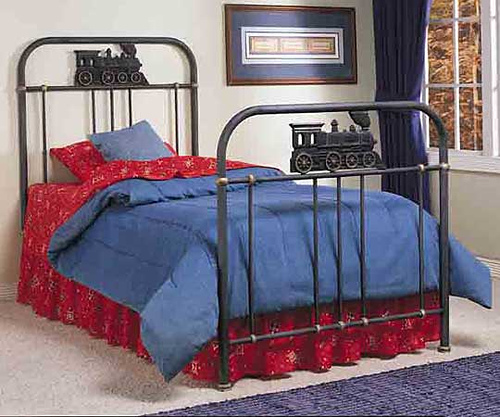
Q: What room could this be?
A: It is a bedroom.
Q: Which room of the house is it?
A: It is a bedroom.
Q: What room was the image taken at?
A: It was taken at the bedroom.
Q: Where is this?
A: This is at the bedroom.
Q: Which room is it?
A: It is a bedroom.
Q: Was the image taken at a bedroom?
A: Yes, it was taken in a bedroom.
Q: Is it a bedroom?
A: Yes, it is a bedroom.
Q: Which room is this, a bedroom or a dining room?
A: It is a bedroom.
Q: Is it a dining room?
A: No, it is a bedroom.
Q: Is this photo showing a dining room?
A: No, the picture is showing a bedroom.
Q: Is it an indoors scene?
A: Yes, it is indoors.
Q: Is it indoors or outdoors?
A: It is indoors.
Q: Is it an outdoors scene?
A: No, it is indoors.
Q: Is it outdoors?
A: No, it is indoors.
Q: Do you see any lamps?
A: No, there are no lamps.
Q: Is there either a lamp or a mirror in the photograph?
A: No, there are no lamps or mirrors.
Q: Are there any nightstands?
A: No, there are no nightstands.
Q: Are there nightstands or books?
A: No, there are no nightstands or books.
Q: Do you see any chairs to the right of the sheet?
A: No, there is a comforter to the right of the sheet.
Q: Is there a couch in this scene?
A: No, there are no couches.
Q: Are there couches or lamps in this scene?
A: No, there are no couches or lamps.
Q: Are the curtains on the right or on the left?
A: The curtains are on the right of the image.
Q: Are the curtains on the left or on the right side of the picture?
A: The curtains are on the right of the image.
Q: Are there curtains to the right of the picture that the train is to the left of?
A: Yes, there are curtains to the right of the picture.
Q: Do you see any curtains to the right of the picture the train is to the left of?
A: Yes, there are curtains to the right of the picture.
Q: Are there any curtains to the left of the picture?
A: No, the curtains are to the right of the picture.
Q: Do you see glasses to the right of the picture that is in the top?
A: No, there are curtains to the right of the picture.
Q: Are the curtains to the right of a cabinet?
A: No, the curtains are to the right of the picture.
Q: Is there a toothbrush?
A: No, there are no toothbrushes.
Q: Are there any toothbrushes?
A: No, there are no toothbrushes.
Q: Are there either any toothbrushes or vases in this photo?
A: No, there are no toothbrushes or vases.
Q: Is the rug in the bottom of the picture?
A: Yes, the rug is in the bottom of the image.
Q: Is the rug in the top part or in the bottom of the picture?
A: The rug is in the bottom of the image.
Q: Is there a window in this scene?
A: Yes, there is a window.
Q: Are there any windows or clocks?
A: Yes, there is a window.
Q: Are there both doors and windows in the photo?
A: No, there is a window but no doors.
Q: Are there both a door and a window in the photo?
A: No, there is a window but no doors.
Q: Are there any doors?
A: No, there are no doors.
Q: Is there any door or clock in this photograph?
A: No, there are no doors or clocks.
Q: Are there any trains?
A: Yes, there is a train.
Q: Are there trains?
A: Yes, there is a train.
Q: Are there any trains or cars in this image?
A: Yes, there is a train.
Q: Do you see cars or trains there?
A: Yes, there is a train.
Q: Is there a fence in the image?
A: No, there are no fences.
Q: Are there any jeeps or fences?
A: No, there are no fences or jeeps.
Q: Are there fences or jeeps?
A: No, there are no fences or jeeps.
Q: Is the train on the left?
A: Yes, the train is on the left of the image.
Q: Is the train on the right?
A: No, the train is on the left of the image.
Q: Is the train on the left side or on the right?
A: The train is on the left of the image.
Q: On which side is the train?
A: The train is on the left of the image.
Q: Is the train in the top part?
A: Yes, the train is in the top of the image.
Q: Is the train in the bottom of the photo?
A: No, the train is in the top of the image.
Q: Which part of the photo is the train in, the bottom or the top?
A: The train is in the top of the image.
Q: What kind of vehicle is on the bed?
A: The vehicle is a train.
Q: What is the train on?
A: The train is on the bed.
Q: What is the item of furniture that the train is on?
A: The piece of furniture is a bed.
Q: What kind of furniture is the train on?
A: The train is on the bed.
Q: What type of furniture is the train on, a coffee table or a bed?
A: The train is on a bed.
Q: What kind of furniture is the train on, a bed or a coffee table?
A: The train is on a bed.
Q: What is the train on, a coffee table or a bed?
A: The train is on a bed.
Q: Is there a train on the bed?
A: Yes, there is a train on the bed.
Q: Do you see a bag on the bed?
A: No, there is a train on the bed.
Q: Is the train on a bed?
A: Yes, the train is on a bed.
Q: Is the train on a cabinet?
A: No, the train is on a bed.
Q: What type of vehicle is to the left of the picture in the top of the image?
A: The vehicle is a train.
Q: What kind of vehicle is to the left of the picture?
A: The vehicle is a train.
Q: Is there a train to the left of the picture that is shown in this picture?
A: Yes, there is a train to the left of the picture.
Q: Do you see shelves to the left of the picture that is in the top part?
A: No, there is a train to the left of the picture.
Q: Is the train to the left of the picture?
A: Yes, the train is to the left of the picture.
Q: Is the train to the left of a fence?
A: No, the train is to the left of the picture.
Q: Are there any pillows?
A: Yes, there is a pillow.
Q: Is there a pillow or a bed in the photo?
A: Yes, there is a pillow.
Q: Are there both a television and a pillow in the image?
A: No, there is a pillow but no televisions.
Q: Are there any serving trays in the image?
A: No, there are no serving trays.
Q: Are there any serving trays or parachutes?
A: No, there are no serving trays or parachutes.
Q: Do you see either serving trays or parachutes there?
A: No, there are no serving trays or parachutes.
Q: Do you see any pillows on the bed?
A: Yes, there is a pillow on the bed.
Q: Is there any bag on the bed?
A: No, there is a pillow on the bed.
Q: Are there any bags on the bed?
A: No, there is a pillow on the bed.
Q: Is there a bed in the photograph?
A: Yes, there is a bed.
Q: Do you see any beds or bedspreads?
A: Yes, there is a bed.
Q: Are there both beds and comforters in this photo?
A: Yes, there are both a bed and a comforter.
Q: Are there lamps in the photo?
A: No, there are no lamps.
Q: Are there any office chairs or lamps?
A: No, there are no lamps or office chairs.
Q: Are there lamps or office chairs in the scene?
A: No, there are no lamps or office chairs.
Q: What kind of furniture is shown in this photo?
A: The furniture is a bed.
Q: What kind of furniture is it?
A: The piece of furniture is a bed.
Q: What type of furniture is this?
A: This is a bed.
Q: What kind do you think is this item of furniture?
A: This is a bed.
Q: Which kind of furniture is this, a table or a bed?
A: This is a bed.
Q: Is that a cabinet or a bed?
A: That is a bed.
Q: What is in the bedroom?
A: The bed is in the bedroom.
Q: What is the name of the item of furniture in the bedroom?
A: The piece of furniture is a bed.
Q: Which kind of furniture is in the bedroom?
A: The piece of furniture is a bed.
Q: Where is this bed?
A: The bed is in the bedroom.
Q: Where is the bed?
A: The bed is in the bedroom.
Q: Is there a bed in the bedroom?
A: Yes, there is a bed in the bedroom.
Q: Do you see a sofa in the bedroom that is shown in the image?
A: No, there is a bed in the bedroom.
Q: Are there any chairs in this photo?
A: No, there are no chairs.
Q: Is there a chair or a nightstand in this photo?
A: No, there are no chairs or nightstands.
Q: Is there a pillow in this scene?
A: Yes, there is a pillow.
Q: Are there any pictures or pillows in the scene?
A: Yes, there is a pillow.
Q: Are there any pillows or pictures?
A: Yes, there is a pillow.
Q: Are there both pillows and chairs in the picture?
A: No, there is a pillow but no chairs.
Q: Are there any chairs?
A: No, there are no chairs.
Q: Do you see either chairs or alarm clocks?
A: No, there are no chairs or alarm clocks.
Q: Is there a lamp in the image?
A: No, there are no lamps.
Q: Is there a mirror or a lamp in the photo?
A: No, there are no lamps or mirrors.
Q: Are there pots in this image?
A: No, there are no pots.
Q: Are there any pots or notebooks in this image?
A: No, there are no pots or notebooks.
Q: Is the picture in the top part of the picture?
A: Yes, the picture is in the top of the image.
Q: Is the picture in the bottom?
A: No, the picture is in the top of the image.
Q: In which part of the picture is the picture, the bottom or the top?
A: The picture is in the top of the image.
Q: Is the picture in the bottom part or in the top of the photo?
A: The picture is in the top of the image.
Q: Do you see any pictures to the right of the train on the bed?
A: Yes, there is a picture to the right of the train.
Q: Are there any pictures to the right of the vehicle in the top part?
A: Yes, there is a picture to the right of the train.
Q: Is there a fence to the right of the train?
A: No, there is a picture to the right of the train.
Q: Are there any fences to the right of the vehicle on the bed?
A: No, there is a picture to the right of the train.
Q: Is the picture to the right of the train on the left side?
A: Yes, the picture is to the right of the train.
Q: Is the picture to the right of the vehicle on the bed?
A: Yes, the picture is to the right of the train.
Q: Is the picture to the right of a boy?
A: No, the picture is to the right of the train.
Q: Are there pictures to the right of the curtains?
A: No, the picture is to the left of the curtains.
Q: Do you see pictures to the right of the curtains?
A: No, the picture is to the left of the curtains.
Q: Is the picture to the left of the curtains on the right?
A: Yes, the picture is to the left of the curtains.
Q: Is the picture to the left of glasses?
A: No, the picture is to the left of the curtains.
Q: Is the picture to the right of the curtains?
A: No, the picture is to the left of the curtains.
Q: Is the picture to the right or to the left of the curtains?
A: The picture is to the left of the curtains.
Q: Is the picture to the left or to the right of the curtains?
A: The picture is to the left of the curtains.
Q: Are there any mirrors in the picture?
A: No, there are no mirrors.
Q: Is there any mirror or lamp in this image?
A: No, there are no mirrors or lamps.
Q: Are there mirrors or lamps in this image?
A: No, there are no mirrors or lamps.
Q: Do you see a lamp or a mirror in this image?
A: No, there are no mirrors or lamps.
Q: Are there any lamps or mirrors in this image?
A: No, there are no mirrors or lamps.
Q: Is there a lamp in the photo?
A: No, there are no lamps.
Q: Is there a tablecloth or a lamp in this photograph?
A: No, there are no lamps or tablecloths.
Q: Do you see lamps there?
A: No, there are no lamps.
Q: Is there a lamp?
A: No, there are no lamps.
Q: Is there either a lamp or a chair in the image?
A: No, there are no lamps or chairs.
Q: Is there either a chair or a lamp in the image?
A: No, there are no lamps or chairs.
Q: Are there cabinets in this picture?
A: No, there are no cabinets.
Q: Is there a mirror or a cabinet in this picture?
A: No, there are no cabinets or mirrors.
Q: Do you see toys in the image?
A: No, there are no toys.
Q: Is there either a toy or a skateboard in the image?
A: No, there are no toys or skateboards.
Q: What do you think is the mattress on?
A: The mattress is on the bed.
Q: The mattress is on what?
A: The mattress is on the bed.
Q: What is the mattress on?
A: The mattress is on the bed.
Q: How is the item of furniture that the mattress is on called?
A: The piece of furniture is a bed.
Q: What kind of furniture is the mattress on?
A: The mattress is on the bed.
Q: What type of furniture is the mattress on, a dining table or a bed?
A: The mattress is on a bed.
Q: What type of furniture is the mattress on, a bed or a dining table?
A: The mattress is on a bed.